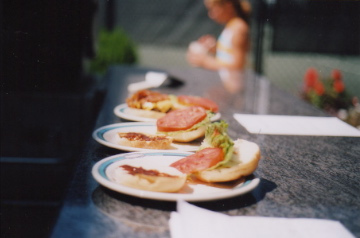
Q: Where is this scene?
A: A restaurant.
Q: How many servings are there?
A: Three.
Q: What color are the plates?
A: White.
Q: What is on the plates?
A: BLT Sandwiches.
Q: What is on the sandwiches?
A: Bacon, lettuce, tomato.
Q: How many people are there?
A: One.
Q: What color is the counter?
A: Grey.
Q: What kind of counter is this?
A: Granite.